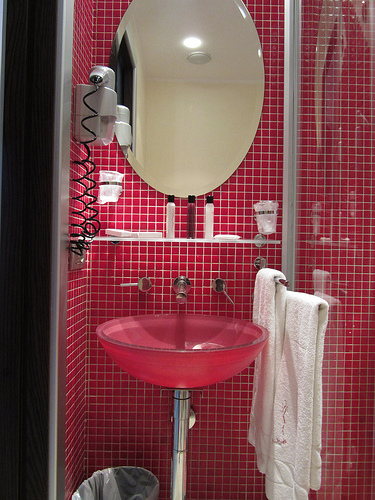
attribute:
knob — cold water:
[195, 276, 261, 321]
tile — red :
[207, 397, 215, 406]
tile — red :
[225, 389, 232, 398]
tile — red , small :
[103, 403, 112, 413]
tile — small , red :
[333, 444, 344, 453]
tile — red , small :
[336, 352, 343, 360]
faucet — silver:
[115, 273, 153, 293]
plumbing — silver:
[165, 388, 199, 497]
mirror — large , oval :
[101, 1, 264, 198]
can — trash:
[70, 464, 163, 494]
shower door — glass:
[292, 21, 372, 366]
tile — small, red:
[330, 414, 344, 425]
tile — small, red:
[335, 368, 349, 381]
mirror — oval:
[110, 7, 280, 196]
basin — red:
[99, 312, 264, 384]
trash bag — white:
[73, 464, 156, 498]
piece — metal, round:
[185, 407, 197, 430]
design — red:
[275, 400, 290, 446]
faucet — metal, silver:
[172, 274, 193, 306]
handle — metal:
[120, 276, 151, 293]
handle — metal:
[213, 278, 238, 310]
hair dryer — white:
[86, 61, 120, 146]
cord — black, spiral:
[76, 84, 101, 262]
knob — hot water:
[119, 278, 152, 292]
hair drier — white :
[76, 58, 152, 168]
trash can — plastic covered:
[71, 462, 161, 498]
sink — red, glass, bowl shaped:
[92, 313, 268, 386]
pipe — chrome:
[170, 387, 196, 498]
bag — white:
[101, 481, 132, 488]